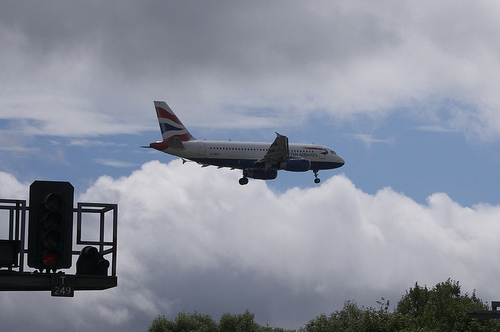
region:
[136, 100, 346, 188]
a white, blue and red airplane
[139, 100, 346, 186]
a white and airplane with a red, white and blue tail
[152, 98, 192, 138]
a red, white and blue tail on the back of the airplane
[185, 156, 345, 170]
the blue bottom of the airplane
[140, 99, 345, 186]
a blue, white and red airplane in the air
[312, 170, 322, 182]
the front wheels on the airplane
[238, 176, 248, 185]
the back wheels on the airplane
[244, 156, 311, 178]
two blue engines under the airplane's wings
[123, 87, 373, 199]
an airplane preparing to land at an airport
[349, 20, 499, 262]
white clouds in the blue sky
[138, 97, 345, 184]
airplane is flying in air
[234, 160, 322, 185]
landing gear is out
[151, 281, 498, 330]
tops of green trees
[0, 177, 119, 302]
stoplight and metal catwalk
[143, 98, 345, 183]
white plane with red and blue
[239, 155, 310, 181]
jet has turbine engines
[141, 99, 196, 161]
tail has red and blue stripes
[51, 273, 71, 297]
number plate under stoplight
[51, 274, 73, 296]
sign has number 249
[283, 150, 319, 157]
writing on airplane side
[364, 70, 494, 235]
the clouds in the sky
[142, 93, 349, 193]
a airplane flying in the sky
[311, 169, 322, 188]
the landing gear of a plane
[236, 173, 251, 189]
the landing gear of a plane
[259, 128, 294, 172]
a wing of a plan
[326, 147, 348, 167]
the nose of a plane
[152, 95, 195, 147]
the tail of a plane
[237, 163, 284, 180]
the enging of a plane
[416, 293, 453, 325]
the leaves of a tree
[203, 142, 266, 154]
the windows on the side of a plane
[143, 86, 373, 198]
Airplane in the sky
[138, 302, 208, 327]
Grene tall tree line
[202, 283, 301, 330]
Grene tall tree line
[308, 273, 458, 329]
Grene tall tree line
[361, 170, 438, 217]
White clouds in the sky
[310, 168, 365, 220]
White clouds in the sky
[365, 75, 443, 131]
White clouds in the sky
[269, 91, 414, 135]
White clouds in the sky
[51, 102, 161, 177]
White clouds in the sky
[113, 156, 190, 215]
White clouds in the sky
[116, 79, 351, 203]
this is a plane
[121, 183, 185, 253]
this is a cloud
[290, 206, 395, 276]
this is a cloud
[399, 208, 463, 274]
this is a cloud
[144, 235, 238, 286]
this is a cloud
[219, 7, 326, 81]
this is a cloud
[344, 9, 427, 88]
this is a cloud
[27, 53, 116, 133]
this is a cloud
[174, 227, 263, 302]
this is a cloud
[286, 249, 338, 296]
this is a cloud